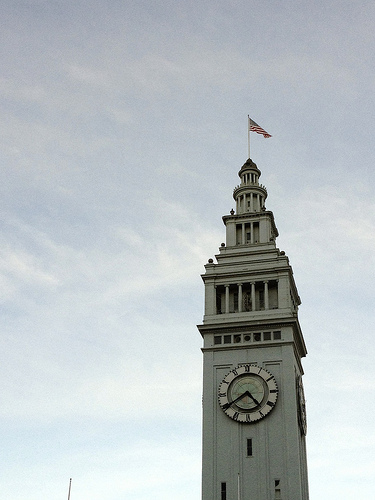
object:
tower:
[194, 113, 310, 499]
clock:
[217, 364, 279, 426]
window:
[245, 435, 255, 458]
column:
[223, 282, 231, 314]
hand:
[245, 390, 261, 406]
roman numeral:
[243, 364, 251, 374]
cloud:
[4, 243, 67, 294]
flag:
[247, 117, 273, 139]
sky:
[0, 0, 375, 500]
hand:
[222, 389, 249, 410]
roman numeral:
[217, 390, 229, 399]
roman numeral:
[220, 378, 231, 386]